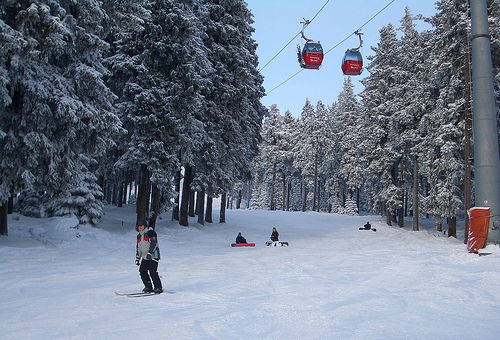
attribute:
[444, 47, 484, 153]
pole — large, grey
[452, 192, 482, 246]
mat — orange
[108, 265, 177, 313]
skis — snow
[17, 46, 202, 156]
trees — snow -covered, pine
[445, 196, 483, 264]
mat — orange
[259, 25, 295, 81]
sky — blue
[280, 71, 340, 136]
day — clear